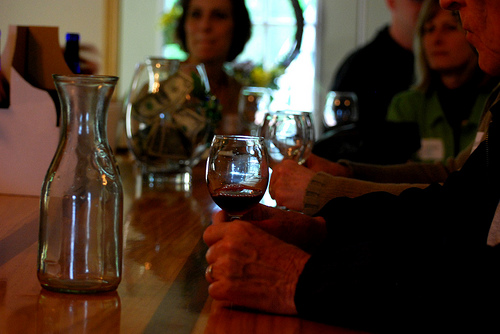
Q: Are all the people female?
A: No, they are both male and female.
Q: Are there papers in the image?
A: No, there are no papers.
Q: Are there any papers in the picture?
A: No, there are no papers.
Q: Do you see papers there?
A: No, there are no papers.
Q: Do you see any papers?
A: No, there are no papers.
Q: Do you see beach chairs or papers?
A: No, there are no papers or beach chairs.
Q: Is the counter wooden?
A: Yes, the counter is wooden.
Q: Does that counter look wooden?
A: Yes, the counter is wooden.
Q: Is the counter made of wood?
A: Yes, the counter is made of wood.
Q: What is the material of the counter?
A: The counter is made of wood.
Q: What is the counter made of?
A: The counter is made of wood.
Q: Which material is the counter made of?
A: The counter is made of wood.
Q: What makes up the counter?
A: The counter is made of wood.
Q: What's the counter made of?
A: The counter is made of wood.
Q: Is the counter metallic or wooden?
A: The counter is wooden.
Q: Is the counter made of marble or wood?
A: The counter is made of wood.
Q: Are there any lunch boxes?
A: No, there are no lunch boxes.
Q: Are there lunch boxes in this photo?
A: No, there are no lunch boxes.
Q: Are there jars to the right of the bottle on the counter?
A: Yes, there is a jar to the right of the bottle.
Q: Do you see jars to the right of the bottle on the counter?
A: Yes, there is a jar to the right of the bottle.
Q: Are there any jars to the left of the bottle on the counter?
A: No, the jar is to the right of the bottle.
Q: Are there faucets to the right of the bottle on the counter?
A: No, there is a jar to the right of the bottle.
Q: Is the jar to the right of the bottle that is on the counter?
A: Yes, the jar is to the right of the bottle.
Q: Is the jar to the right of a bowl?
A: No, the jar is to the right of the bottle.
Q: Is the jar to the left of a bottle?
A: No, the jar is to the right of a bottle.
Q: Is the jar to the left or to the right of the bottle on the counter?
A: The jar is to the right of the bottle.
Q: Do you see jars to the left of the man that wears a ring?
A: Yes, there is a jar to the left of the man.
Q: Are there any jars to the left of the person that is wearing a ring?
A: Yes, there is a jar to the left of the man.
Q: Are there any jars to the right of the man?
A: No, the jar is to the left of the man.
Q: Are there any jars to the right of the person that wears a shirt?
A: No, the jar is to the left of the man.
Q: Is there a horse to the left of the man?
A: No, there is a jar to the left of the man.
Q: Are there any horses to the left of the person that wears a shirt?
A: No, there is a jar to the left of the man.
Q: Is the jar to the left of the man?
A: Yes, the jar is to the left of the man.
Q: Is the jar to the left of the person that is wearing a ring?
A: Yes, the jar is to the left of the man.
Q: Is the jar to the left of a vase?
A: No, the jar is to the left of the man.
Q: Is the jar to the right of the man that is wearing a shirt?
A: No, the jar is to the left of the man.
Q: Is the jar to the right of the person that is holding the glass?
A: No, the jar is to the left of the man.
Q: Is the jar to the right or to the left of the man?
A: The jar is to the left of the man.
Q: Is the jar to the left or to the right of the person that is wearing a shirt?
A: The jar is to the left of the man.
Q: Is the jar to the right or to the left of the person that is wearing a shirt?
A: The jar is to the left of the man.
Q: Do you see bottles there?
A: Yes, there is a bottle.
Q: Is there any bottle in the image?
A: Yes, there is a bottle.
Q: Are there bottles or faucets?
A: Yes, there is a bottle.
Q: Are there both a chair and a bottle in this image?
A: No, there is a bottle but no chairs.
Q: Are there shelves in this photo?
A: No, there are no shelves.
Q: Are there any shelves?
A: No, there are no shelves.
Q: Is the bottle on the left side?
A: Yes, the bottle is on the left of the image.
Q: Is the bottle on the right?
A: No, the bottle is on the left of the image.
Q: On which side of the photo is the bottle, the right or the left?
A: The bottle is on the left of the image.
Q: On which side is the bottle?
A: The bottle is on the left of the image.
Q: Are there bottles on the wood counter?
A: Yes, there is a bottle on the counter.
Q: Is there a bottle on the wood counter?
A: Yes, there is a bottle on the counter.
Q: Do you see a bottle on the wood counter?
A: Yes, there is a bottle on the counter.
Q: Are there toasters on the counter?
A: No, there is a bottle on the counter.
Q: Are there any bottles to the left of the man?
A: Yes, there is a bottle to the left of the man.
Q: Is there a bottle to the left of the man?
A: Yes, there is a bottle to the left of the man.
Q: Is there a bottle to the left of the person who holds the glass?
A: Yes, there is a bottle to the left of the man.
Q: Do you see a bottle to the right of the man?
A: No, the bottle is to the left of the man.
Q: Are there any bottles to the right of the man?
A: No, the bottle is to the left of the man.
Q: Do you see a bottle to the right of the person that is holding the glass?
A: No, the bottle is to the left of the man.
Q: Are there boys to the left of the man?
A: No, there is a bottle to the left of the man.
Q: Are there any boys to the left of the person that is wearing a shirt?
A: No, there is a bottle to the left of the man.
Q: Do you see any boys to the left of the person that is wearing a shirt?
A: No, there is a bottle to the left of the man.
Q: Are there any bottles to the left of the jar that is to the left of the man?
A: Yes, there is a bottle to the left of the jar.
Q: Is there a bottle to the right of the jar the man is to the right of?
A: No, the bottle is to the left of the jar.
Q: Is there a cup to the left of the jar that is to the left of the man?
A: No, there is a bottle to the left of the jar.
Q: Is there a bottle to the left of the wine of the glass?
A: Yes, there is a bottle to the left of the wine.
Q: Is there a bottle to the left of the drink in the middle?
A: Yes, there is a bottle to the left of the wine.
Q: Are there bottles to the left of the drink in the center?
A: Yes, there is a bottle to the left of the wine.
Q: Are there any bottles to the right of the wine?
A: No, the bottle is to the left of the wine.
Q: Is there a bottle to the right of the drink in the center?
A: No, the bottle is to the left of the wine.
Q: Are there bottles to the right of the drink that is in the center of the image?
A: No, the bottle is to the left of the wine.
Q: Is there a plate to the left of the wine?
A: No, there is a bottle to the left of the wine.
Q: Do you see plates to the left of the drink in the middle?
A: No, there is a bottle to the left of the wine.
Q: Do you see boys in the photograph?
A: No, there are no boys.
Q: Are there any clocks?
A: No, there are no clocks.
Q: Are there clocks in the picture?
A: No, there are no clocks.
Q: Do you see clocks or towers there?
A: No, there are no clocks or towers.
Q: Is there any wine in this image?
A: Yes, there is wine.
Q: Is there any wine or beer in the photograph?
A: Yes, there is wine.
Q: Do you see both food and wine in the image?
A: No, there is wine but no food.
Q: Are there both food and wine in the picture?
A: No, there is wine but no food.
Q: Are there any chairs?
A: No, there are no chairs.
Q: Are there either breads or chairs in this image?
A: No, there are no chairs or breads.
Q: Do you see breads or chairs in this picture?
A: No, there are no chairs or breads.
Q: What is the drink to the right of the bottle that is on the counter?
A: The drink is wine.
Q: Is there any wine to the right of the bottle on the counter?
A: Yes, there is wine to the right of the bottle.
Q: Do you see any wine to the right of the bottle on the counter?
A: Yes, there is wine to the right of the bottle.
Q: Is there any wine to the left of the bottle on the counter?
A: No, the wine is to the right of the bottle.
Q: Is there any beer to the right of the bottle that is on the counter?
A: No, there is wine to the right of the bottle.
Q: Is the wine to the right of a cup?
A: No, the wine is to the right of the bottle.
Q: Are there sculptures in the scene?
A: No, there are no sculptures.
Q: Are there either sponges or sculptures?
A: No, there are no sculptures or sponges.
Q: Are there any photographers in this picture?
A: No, there are no photographers.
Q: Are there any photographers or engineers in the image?
A: No, there are no photographers or engineers.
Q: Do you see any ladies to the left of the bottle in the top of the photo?
A: No, the lady is to the right of the bottle.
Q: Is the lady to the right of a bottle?
A: Yes, the lady is to the right of a bottle.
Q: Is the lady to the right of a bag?
A: No, the lady is to the right of a bottle.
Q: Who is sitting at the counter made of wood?
A: The lady is sitting at the counter.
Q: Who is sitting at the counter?
A: The lady is sitting at the counter.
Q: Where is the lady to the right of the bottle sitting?
A: The lady is sitting at the counter.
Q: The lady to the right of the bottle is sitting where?
A: The lady is sitting at the counter.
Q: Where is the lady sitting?
A: The lady is sitting at the counter.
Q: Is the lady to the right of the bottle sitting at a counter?
A: Yes, the lady is sitting at a counter.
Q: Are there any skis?
A: No, there are no skis.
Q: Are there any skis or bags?
A: No, there are no skis or bags.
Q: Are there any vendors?
A: No, there are no vendors.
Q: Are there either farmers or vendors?
A: No, there are no vendors or farmers.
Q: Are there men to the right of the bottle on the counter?
A: Yes, there is a man to the right of the bottle.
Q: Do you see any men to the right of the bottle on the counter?
A: Yes, there is a man to the right of the bottle.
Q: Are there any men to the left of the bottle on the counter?
A: No, the man is to the right of the bottle.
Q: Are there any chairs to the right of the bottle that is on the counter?
A: No, there is a man to the right of the bottle.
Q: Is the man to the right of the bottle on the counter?
A: Yes, the man is to the right of the bottle.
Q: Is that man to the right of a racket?
A: No, the man is to the right of the bottle.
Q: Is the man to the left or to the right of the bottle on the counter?
A: The man is to the right of the bottle.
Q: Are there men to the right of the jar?
A: Yes, there is a man to the right of the jar.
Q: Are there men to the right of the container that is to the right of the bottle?
A: Yes, there is a man to the right of the jar.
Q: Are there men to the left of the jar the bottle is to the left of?
A: No, the man is to the right of the jar.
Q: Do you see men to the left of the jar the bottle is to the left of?
A: No, the man is to the right of the jar.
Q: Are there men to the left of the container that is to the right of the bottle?
A: No, the man is to the right of the jar.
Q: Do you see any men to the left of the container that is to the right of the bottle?
A: No, the man is to the right of the jar.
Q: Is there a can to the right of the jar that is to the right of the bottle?
A: No, there is a man to the right of the jar.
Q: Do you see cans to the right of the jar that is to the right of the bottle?
A: No, there is a man to the right of the jar.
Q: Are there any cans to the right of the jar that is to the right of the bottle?
A: No, there is a man to the right of the jar.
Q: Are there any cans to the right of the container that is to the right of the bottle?
A: No, there is a man to the right of the jar.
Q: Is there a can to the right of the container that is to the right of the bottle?
A: No, there is a man to the right of the jar.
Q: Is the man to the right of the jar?
A: Yes, the man is to the right of the jar.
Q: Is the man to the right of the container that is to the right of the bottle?
A: Yes, the man is to the right of the jar.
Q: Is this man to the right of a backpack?
A: No, the man is to the right of the jar.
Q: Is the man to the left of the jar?
A: No, the man is to the right of the jar.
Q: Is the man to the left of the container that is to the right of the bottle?
A: No, the man is to the right of the jar.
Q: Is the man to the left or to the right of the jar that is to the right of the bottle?
A: The man is to the right of the jar.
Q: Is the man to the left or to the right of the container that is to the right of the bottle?
A: The man is to the right of the jar.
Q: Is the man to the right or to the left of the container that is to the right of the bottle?
A: The man is to the right of the jar.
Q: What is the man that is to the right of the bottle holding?
A: The man is holding the glass.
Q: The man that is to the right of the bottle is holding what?
A: The man is holding the glass.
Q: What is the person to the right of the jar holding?
A: The man is holding the glass.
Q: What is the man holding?
A: The man is holding the glass.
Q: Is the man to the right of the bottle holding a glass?
A: Yes, the man is holding a glass.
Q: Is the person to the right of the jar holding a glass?
A: Yes, the man is holding a glass.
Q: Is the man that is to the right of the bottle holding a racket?
A: No, the man is holding a glass.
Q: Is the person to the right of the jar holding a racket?
A: No, the man is holding a glass.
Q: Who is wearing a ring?
A: The man is wearing a ring.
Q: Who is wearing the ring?
A: The man is wearing a ring.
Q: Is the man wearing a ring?
A: Yes, the man is wearing a ring.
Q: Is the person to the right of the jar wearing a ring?
A: Yes, the man is wearing a ring.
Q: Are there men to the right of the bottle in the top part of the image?
A: Yes, there is a man to the right of the bottle.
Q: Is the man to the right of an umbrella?
A: No, the man is to the right of the bottle.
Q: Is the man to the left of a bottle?
A: No, the man is to the right of a bottle.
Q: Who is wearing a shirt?
A: The man is wearing a shirt.